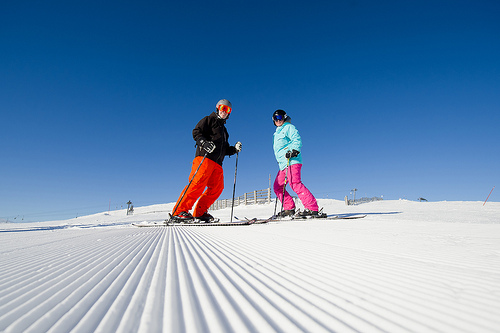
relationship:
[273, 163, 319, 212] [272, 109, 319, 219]
pants worn by woman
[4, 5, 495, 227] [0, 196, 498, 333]
sky above ground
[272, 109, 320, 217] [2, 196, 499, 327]
female skier on ground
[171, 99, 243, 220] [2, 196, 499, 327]
man on ground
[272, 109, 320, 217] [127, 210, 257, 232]
female skier on skis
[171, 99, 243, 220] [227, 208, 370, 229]
man on skis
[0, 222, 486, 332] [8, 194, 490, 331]
groves on snow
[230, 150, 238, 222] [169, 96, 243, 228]
ski pole on man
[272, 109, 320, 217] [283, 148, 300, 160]
female skier on gloves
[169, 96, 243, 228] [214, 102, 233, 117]
man on goggles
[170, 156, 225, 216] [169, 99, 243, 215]
pants on person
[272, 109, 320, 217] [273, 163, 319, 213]
female skier on pants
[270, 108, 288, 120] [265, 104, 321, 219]
helmet on person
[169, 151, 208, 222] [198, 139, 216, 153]
ski pole in hand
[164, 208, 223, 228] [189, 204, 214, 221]
equipment attached feet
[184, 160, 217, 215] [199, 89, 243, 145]
pants on skier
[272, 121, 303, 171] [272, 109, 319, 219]
blue jacket on woman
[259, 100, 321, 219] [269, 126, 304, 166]
female skier wearing coat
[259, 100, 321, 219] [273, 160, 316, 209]
female skier wearing pants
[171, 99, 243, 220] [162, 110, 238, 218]
man wearing clothing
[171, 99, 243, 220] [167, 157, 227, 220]
man wearing pants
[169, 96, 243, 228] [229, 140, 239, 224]
man holding pole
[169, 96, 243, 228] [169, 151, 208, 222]
man holding ski pole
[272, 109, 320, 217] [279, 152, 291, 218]
female skier holding ski pole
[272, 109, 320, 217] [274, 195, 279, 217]
female skier holding ski pole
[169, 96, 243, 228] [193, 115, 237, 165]
man wears black jacket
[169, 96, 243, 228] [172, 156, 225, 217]
man wearing pants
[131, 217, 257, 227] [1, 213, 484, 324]
skis on ground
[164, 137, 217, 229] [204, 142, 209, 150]
ski pole in hand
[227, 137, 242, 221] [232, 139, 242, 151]
ski pole in hand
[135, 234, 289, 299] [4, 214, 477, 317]
lines in snow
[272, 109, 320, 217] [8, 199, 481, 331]
female skier skiing on slope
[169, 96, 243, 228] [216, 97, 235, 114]
man wearing helmet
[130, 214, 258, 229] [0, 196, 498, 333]
skis on ground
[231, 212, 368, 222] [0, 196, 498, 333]
skis on ground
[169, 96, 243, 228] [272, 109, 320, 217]
man and female skier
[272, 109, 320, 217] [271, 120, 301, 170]
female skier wearing blue jacket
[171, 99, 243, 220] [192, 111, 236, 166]
man wearing black jacket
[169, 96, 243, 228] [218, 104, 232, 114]
man wearing goggles